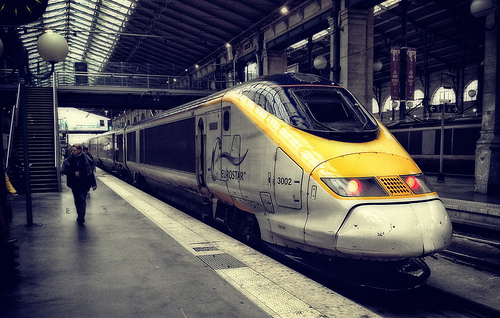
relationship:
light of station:
[38, 32, 68, 62] [1, 1, 498, 314]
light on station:
[302, 45, 342, 75] [16, 8, 480, 253]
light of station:
[364, 37, 403, 91] [15, 15, 481, 306]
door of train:
[263, 132, 328, 264] [90, 52, 444, 268]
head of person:
[55, 127, 105, 161] [59, 139, 158, 248]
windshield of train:
[237, 55, 400, 144] [80, 81, 484, 303]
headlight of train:
[330, 148, 456, 208] [90, 58, 452, 313]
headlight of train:
[393, 155, 457, 248] [70, 43, 453, 283]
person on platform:
[57, 129, 116, 254] [10, 171, 198, 314]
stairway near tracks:
[12, 75, 97, 216] [447, 213, 481, 293]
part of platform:
[54, 246, 195, 300] [109, 229, 211, 297]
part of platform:
[29, 245, 139, 289] [14, 250, 92, 310]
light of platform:
[34, 28, 101, 103] [49, 204, 99, 263]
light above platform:
[267, 4, 307, 24] [420, 155, 481, 197]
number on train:
[249, 149, 306, 206] [114, 45, 482, 278]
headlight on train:
[310, 178, 381, 210] [120, 65, 466, 283]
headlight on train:
[395, 157, 475, 206] [114, 60, 455, 275]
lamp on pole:
[34, 24, 94, 74] [23, 55, 68, 89]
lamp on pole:
[34, 16, 82, 69] [25, 61, 75, 97]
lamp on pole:
[302, 50, 349, 86] [319, 32, 354, 80]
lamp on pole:
[365, 45, 385, 83] [368, 75, 386, 101]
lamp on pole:
[460, 84, 479, 105] [471, 97, 484, 129]